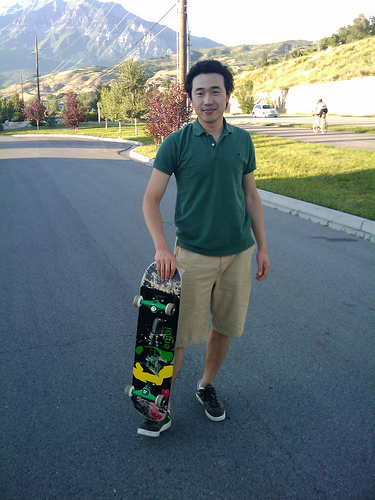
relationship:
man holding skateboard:
[138, 60, 271, 446] [136, 261, 180, 423]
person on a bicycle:
[310, 97, 331, 120] [310, 114, 330, 134]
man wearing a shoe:
[138, 60, 271, 446] [194, 380, 228, 423]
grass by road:
[254, 138, 366, 202] [0, 135, 373, 497]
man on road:
[138, 60, 271, 446] [0, 135, 373, 497]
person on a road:
[310, 97, 331, 120] [224, 113, 374, 151]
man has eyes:
[138, 60, 271, 446] [193, 88, 232, 102]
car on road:
[254, 101, 283, 121] [226, 110, 373, 133]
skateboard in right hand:
[136, 261, 180, 423] [151, 252, 184, 279]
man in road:
[138, 60, 271, 446] [0, 135, 373, 497]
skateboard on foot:
[136, 261, 180, 423] [135, 411, 177, 438]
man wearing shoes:
[138, 60, 271, 446] [135, 390, 235, 437]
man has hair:
[138, 60, 271, 446] [178, 62, 238, 99]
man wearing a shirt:
[138, 60, 271, 446] [151, 123, 261, 254]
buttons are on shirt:
[203, 132, 218, 150] [151, 123, 261, 254]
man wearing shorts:
[138, 60, 271, 446] [173, 242, 255, 343]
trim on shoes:
[141, 419, 178, 437] [135, 390, 235, 437]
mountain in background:
[1, 3, 225, 79] [1, 2, 374, 137]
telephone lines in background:
[36, 0, 177, 93] [1, 2, 374, 137]